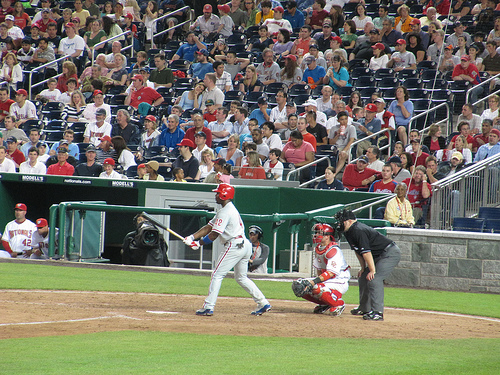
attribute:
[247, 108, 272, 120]
shirt — blue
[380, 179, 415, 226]
man — bald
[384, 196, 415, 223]
shirt — yellow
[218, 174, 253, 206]
hat — red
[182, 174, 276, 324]
batter — black, waiting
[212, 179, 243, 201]
helmet — red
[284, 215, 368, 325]
catcher — crouching, scrunched down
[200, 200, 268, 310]
uniform — white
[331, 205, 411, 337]
umpire — standing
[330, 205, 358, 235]
helmet — black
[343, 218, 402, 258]
shirt — black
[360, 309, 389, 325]
shoe — black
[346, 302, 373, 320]
shoe — black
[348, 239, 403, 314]
pants — gray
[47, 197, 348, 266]
railing — green, padded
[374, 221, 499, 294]
wall — gray, stone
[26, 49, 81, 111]
railing — metal, silver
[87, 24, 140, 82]
railing — metal, silver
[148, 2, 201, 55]
railing — metal, silver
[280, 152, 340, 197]
railing — metal, silver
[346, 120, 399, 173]
railing — metal, silver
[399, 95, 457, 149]
railing — metal, silver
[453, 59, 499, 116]
railing — metal, silver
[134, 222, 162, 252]
camera — video